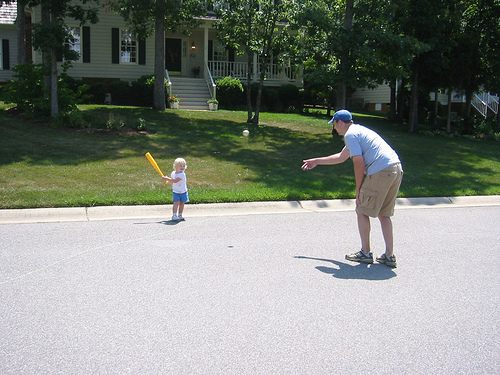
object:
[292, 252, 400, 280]
shadow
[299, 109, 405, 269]
man standing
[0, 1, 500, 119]
house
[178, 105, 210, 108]
steps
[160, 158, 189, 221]
girl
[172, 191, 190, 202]
shorts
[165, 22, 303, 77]
porch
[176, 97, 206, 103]
steps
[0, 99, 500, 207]
grass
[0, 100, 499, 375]
ground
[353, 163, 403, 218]
shorts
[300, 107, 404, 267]
man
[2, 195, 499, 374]
street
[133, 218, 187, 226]
shadow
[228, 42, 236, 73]
shutter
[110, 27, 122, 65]
shutter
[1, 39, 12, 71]
shutter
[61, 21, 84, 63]
window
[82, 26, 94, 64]
window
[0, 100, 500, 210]
yard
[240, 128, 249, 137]
ball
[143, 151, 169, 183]
bat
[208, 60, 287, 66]
railing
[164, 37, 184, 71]
door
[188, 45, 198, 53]
porch light